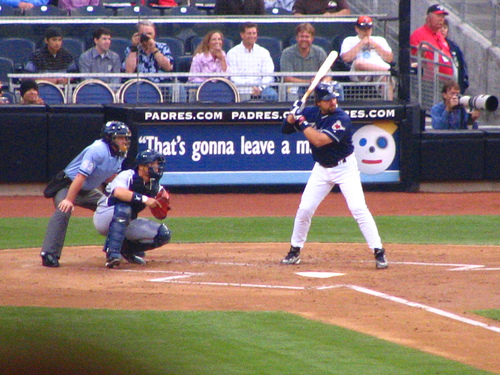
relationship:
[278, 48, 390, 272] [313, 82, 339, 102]
baseball batter wearing helmet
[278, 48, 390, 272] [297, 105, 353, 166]
baseball batter wearing jersey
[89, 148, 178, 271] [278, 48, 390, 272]
catcher watching baseball batter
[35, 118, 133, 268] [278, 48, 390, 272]
referee watching baseball batter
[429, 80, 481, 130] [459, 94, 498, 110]
man has large/telephoto lens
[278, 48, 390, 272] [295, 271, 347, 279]
baseball batter standing at home plate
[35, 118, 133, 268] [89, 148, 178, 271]
referee stands behind catcher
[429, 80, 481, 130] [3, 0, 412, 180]
man in stands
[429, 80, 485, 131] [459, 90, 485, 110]
man using a large/telephoto lens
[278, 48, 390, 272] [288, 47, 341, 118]
baseball batter holding bat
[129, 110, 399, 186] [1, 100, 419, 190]
advertisement on wall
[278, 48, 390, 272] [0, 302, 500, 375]
baseball batter playing baseball on area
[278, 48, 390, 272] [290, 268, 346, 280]
baseball batter standing at home plate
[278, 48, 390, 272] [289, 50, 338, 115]
baseball batter with baseball bat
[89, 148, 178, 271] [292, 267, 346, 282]
catcher squatting behind home plate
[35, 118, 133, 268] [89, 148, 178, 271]
referee standing behind catcher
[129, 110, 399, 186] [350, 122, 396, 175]
advertisement with a clown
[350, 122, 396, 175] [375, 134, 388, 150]
clown with black eye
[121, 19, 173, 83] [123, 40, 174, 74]
man wearing blue/white shirt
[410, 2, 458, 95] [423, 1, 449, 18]
man wearing shirt/cap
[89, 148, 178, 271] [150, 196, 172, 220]
catcher wearing glove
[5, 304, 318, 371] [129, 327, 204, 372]
area of green grass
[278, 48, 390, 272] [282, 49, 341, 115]
baseball batter holding bat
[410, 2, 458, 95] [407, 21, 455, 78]
man wearing shirt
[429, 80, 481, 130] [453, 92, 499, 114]
man looking into lense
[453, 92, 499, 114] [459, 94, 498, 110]
lense on large/telephoto lens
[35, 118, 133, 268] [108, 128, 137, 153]
referee wearing face mask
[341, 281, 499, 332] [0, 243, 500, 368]
line on dirt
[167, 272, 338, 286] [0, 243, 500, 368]
line on dirt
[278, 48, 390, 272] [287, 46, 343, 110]
baseball batter holding bat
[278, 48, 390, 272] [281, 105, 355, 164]
baseball batter wearing jersey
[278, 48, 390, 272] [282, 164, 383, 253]
baseball batter wearing pants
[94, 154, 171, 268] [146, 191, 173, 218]
catcher holding glove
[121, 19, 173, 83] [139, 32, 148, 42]
man holding camera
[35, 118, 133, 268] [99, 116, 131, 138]
referee wearing helmet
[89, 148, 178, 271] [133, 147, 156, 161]
catcher wearing helmet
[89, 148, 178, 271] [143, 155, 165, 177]
catcher wearing mask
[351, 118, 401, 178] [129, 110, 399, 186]
face on advertisement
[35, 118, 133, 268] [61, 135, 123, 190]
referee wearing shirt